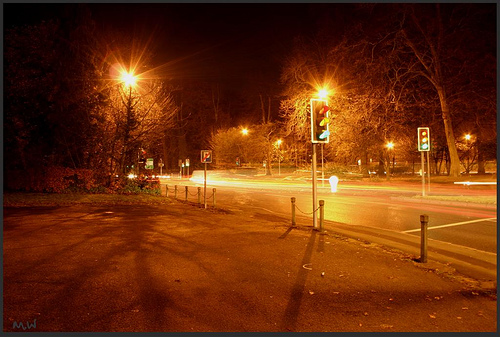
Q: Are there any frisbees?
A: No, there are no frisbees.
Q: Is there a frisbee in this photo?
A: No, there are no frisbees.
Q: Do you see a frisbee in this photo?
A: No, there are no frisbees.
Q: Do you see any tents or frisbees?
A: No, there are no frisbees or tents.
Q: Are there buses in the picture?
A: No, there are no buses.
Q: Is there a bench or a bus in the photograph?
A: No, there are no buses or benches.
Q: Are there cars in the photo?
A: No, there are no cars.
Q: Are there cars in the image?
A: No, there are no cars.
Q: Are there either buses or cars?
A: No, there are no cars or buses.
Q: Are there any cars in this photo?
A: No, there are no cars.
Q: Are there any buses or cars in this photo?
A: No, there are no cars or buses.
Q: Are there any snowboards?
A: No, there are no snowboards.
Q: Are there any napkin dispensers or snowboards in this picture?
A: No, there are no snowboards or napkin dispensers.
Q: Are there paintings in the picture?
A: No, there are no paintings.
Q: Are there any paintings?
A: No, there are no paintings.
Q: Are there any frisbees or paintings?
A: No, there are no paintings or frisbees.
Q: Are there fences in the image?
A: Yes, there is a fence.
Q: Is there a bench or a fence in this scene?
A: Yes, there is a fence.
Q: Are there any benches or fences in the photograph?
A: Yes, there is a fence.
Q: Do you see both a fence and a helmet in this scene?
A: No, there is a fence but no helmets.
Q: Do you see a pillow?
A: No, there are no pillows.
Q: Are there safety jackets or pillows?
A: No, there are no pillows or safety jackets.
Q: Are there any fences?
A: Yes, there is a fence.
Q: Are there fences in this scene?
A: Yes, there is a fence.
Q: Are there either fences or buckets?
A: Yes, there is a fence.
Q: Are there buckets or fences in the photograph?
A: Yes, there is a fence.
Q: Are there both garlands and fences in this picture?
A: No, there is a fence but no garlands.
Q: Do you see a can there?
A: No, there are no cans.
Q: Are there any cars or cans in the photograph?
A: No, there are no cans or cars.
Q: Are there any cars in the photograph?
A: No, there are no cars.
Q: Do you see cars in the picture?
A: No, there are no cars.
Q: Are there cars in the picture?
A: No, there are no cars.